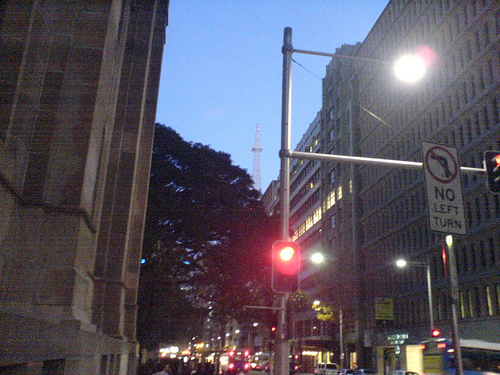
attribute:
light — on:
[374, 44, 443, 96]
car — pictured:
[224, 356, 252, 373]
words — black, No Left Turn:
[429, 183, 464, 232]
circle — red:
[418, 145, 462, 192]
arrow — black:
[418, 126, 479, 243]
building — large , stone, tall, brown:
[2, 2, 169, 372]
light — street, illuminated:
[396, 258, 426, 318]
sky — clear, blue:
[168, 4, 382, 191]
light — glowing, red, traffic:
[396, 57, 429, 82]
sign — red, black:
[412, 136, 467, 242]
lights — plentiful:
[159, 319, 458, 371]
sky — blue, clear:
[178, 3, 267, 128]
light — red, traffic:
[275, 241, 295, 293]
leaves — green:
[195, 150, 203, 158]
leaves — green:
[211, 177, 222, 190]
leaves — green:
[205, 217, 235, 233]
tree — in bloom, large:
[145, 121, 274, 310]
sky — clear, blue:
[152, 0, 394, 209]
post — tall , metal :
[273, 25, 297, 373]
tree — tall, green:
[139, 114, 275, 356]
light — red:
[271, 239, 301, 269]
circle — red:
[426, 141, 460, 186]